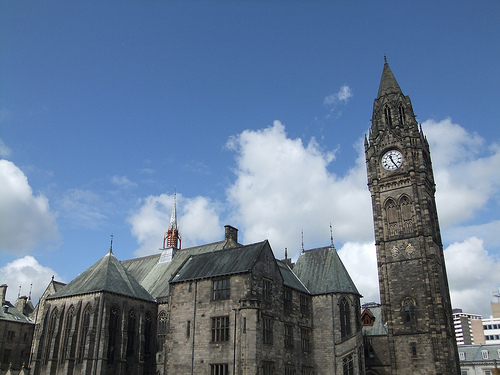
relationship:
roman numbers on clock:
[381, 150, 400, 170] [380, 145, 403, 172]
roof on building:
[167, 248, 264, 277] [164, 239, 366, 371]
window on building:
[225, 316, 229, 328] [363, 49, 459, 373]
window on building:
[83, 302, 100, 370] [363, 49, 459, 373]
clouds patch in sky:
[235, 130, 365, 249] [0, 0, 499, 282]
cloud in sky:
[0, 159, 62, 247] [0, 0, 499, 282]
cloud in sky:
[127, 186, 228, 261] [0, 0, 499, 282]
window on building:
[225, 316, 229, 328] [1, 47, 465, 373]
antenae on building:
[328, 222, 333, 244] [290, 245, 364, 373]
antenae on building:
[301, 227, 303, 249] [290, 245, 364, 373]